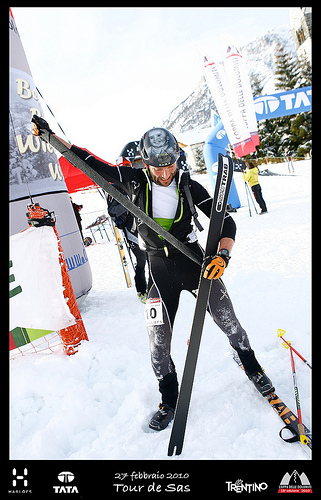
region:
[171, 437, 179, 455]
Ski end touching the snow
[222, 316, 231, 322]
Ice on the thigh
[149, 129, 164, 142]
Face of person on head gear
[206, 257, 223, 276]
Hand in a glove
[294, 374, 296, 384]
Ski pole on the snow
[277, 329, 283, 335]
Yellow end of pole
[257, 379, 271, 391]
Foot on the ski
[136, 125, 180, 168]
this man is wearing a black and white helmit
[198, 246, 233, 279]
the man is wearing a black and yellow glove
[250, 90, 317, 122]
there is a blue and white banner in the background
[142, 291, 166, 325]
there is a white and black number sign on the mans leg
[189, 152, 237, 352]
the man is holding a white and black ski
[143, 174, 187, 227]
the man is wearing a white and green shirt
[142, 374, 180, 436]
the man is wearing black boots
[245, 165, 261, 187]
this person is wearing a yellow jacket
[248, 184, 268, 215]
this person is wearing black pants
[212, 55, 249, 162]
there are red and white signs in the background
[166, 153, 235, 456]
A long black ski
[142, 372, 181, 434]
A mans black shoe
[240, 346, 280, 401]
Mens black ski shoe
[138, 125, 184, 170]
A black helmet for sports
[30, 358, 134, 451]
White snow on ground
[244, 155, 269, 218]
A woman in yellow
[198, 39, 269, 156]
A advert flag flying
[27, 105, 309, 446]
A skiier with skis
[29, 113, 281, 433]
there is a man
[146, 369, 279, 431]
the man have on gray sneakers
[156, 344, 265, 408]
the man have on black legs warmer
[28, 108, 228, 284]
the man have on gold and black gloves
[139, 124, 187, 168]
the man have on picture hat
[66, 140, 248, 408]
the man have on black suit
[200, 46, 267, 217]
lady holding two signs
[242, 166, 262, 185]
lady have on yellow shirt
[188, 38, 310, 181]
there are green pine trees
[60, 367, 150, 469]
floor is covered of snow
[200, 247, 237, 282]
the gloves are orange in color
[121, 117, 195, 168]
helmet is black in color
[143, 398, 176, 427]
shoes are black in color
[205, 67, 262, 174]
the boards are white in color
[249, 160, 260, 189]
sweater is yellow in color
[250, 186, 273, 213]
pants are black in color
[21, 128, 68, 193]
words are written in white color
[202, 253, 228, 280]
yellow glove on a man's left hand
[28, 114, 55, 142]
yellow and black glove on a man's right hand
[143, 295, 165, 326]
number bib on a man's leg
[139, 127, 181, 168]
grey ski helmet on a man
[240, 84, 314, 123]
blue and white banner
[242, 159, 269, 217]
person with a yellow shirt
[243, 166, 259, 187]
long sleeved yellow shirt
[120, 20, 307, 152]
snow covered mountain peak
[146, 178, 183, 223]
man's white shirt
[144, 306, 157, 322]
number 10 on a sticker